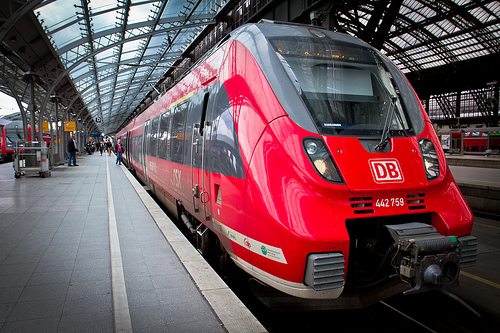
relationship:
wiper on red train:
[373, 73, 408, 151] [112, 19, 479, 312]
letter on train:
[374, 162, 388, 178] [108, 19, 490, 308]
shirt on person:
[116, 140, 122, 151] [112, 136, 124, 165]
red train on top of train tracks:
[112, 19, 479, 312] [272, 292, 491, 333]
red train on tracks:
[112, 19, 479, 312] [415, 115, 497, 332]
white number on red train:
[375, 197, 405, 207] [112, 19, 479, 312]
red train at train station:
[112, 19, 479, 312] [8, 0, 497, 327]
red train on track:
[112, 19, 479, 312] [247, 280, 493, 331]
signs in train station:
[28, 103, 96, 145] [8, 0, 497, 327]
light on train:
[301, 135, 347, 185] [196, 14, 475, 294]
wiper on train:
[372, 97, 404, 163] [140, 30, 435, 294]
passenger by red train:
[115, 138, 125, 165] [112, 19, 479, 312]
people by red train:
[66, 134, 79, 166] [112, 19, 479, 312]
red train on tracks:
[115, 20, 480, 312] [324, 301, 459, 331]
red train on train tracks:
[112, 19, 479, 312] [293, 292, 493, 329]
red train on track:
[112, 19, 479, 312] [273, 297, 495, 331]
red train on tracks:
[112, 19, 479, 312] [109, 139, 496, 333]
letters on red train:
[164, 165, 184, 188] [112, 19, 479, 312]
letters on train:
[164, 165, 184, 188] [0, 107, 87, 154]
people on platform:
[66, 134, 79, 166] [0, 129, 490, 331]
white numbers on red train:
[373, 195, 409, 210] [112, 19, 479, 312]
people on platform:
[64, 134, 79, 166] [1, 143, 270, 331]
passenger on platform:
[115, 138, 125, 165] [1, 143, 270, 331]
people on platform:
[98, 138, 104, 155] [1, 143, 270, 331]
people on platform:
[103, 135, 112, 155] [1, 143, 270, 331]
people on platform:
[93, 140, 100, 151] [1, 143, 270, 331]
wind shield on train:
[288, 56, 391, 141] [99, 26, 429, 298]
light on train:
[299, 135, 344, 188] [108, 19, 490, 308]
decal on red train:
[368, 157, 403, 184] [112, 19, 479, 312]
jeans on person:
[68, 152, 75, 163] [65, 134, 77, 166]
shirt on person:
[114, 144, 123, 153] [113, 137, 125, 164]